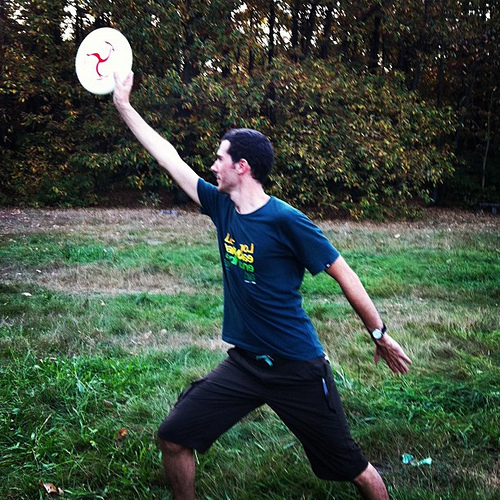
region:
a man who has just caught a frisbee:
[47, 20, 428, 495]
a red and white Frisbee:
[73, 28, 132, 93]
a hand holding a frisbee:
[63, 24, 140, 118]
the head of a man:
[197, 114, 288, 218]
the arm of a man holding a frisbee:
[57, 18, 208, 208]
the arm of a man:
[303, 216, 431, 379]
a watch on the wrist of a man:
[360, 318, 390, 345]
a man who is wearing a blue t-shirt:
[193, 118, 343, 366]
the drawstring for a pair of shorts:
[256, 346, 276, 371]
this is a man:
[124, 117, 409, 498]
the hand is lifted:
[107, 74, 216, 204]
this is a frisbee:
[74, 28, 134, 90]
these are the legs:
[167, 385, 351, 498]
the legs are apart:
[157, 380, 364, 498]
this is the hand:
[324, 250, 424, 377]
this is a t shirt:
[262, 235, 304, 334]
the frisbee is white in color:
[72, 27, 135, 97]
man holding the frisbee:
[59, 23, 423, 478]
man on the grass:
[76, 26, 423, 496]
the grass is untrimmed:
[10, 202, 498, 460]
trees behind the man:
[14, 6, 467, 224]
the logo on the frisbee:
[81, 39, 113, 79]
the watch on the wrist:
[363, 315, 391, 342]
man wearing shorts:
[166, 344, 368, 484]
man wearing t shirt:
[198, 175, 334, 355]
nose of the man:
[206, 162, 215, 172]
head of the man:
[199, 118, 279, 204]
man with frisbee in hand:
[58, 18, 420, 490]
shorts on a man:
[154, 336, 391, 483]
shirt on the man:
[201, 183, 342, 363]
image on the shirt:
[216, 238, 258, 273]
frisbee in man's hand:
[58, 20, 143, 97]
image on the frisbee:
[87, 38, 119, 79]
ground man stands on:
[8, 209, 484, 486]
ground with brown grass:
[18, 215, 216, 242]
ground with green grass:
[6, 371, 128, 477]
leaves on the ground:
[36, 425, 141, 493]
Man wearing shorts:
[157, 344, 381, 486]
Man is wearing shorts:
[157, 324, 374, 486]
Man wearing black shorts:
[155, 333, 374, 484]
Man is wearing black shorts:
[155, 332, 373, 484]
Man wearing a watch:
[364, 320, 395, 341]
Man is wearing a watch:
[365, 317, 390, 344]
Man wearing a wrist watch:
[366, 317, 391, 347]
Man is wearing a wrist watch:
[366, 320, 391, 342]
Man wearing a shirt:
[195, 167, 348, 369]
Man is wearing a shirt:
[194, 174, 349, 365]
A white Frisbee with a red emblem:
[71, 25, 131, 92]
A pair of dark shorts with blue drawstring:
[156, 347, 371, 477]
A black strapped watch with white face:
[368, 324, 385, 339]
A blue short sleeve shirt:
[193, 178, 335, 359]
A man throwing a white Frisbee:
[76, 27, 426, 497]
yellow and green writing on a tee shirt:
[219, 234, 257, 274]